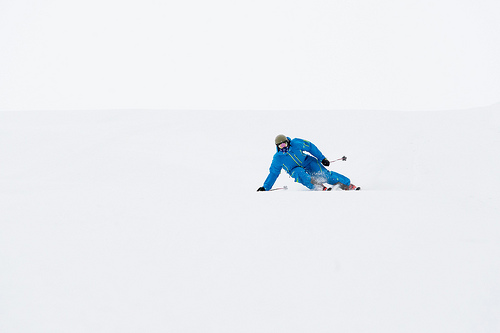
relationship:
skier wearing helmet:
[257, 135, 360, 192] [276, 136, 289, 151]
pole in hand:
[331, 158, 346, 165] [322, 159, 330, 167]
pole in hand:
[267, 187, 287, 191] [255, 188, 267, 191]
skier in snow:
[257, 135, 360, 192] [0, 107, 490, 316]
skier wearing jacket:
[257, 135, 360, 192] [259, 136, 354, 191]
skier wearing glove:
[257, 135, 360, 192] [321, 160, 330, 166]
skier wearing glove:
[257, 135, 360, 192] [257, 186, 264, 192]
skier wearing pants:
[257, 135, 360, 192] [289, 157, 351, 190]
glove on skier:
[321, 160, 330, 166] [257, 135, 360, 192]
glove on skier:
[257, 186, 264, 192] [257, 135, 360, 192]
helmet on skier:
[276, 136, 289, 151] [257, 135, 360, 192]